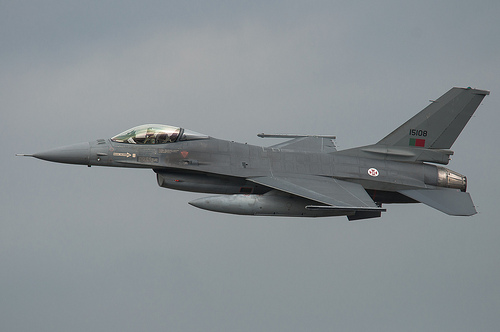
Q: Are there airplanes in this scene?
A: Yes, there is an airplane.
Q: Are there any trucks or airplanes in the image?
A: Yes, there is an airplane.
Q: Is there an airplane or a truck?
A: Yes, there is an airplane.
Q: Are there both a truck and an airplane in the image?
A: No, there is an airplane but no trucks.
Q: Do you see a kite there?
A: No, there are no kites.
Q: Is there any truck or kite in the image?
A: No, there are no kites or trucks.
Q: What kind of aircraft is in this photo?
A: The aircraft is an airplane.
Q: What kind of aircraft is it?
A: The aircraft is an airplane.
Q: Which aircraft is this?
A: That is an airplane.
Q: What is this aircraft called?
A: That is an airplane.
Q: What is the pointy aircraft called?
A: The aircraft is an airplane.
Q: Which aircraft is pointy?
A: The aircraft is an airplane.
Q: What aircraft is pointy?
A: The aircraft is an airplane.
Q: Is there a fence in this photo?
A: No, there are no fences.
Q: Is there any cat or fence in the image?
A: No, there are no fences or cats.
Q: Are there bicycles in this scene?
A: No, there are no bicycles.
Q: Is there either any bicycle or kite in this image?
A: No, there are no bicycles or kites.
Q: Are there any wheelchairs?
A: No, there are no wheelchairs.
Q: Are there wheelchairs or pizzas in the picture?
A: No, there are no wheelchairs or pizzas.